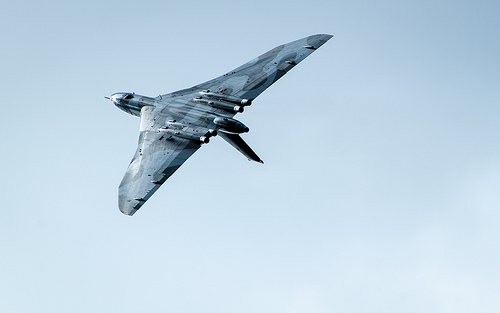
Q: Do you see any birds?
A: No, there are no birds.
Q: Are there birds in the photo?
A: No, there are no birds.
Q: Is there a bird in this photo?
A: No, there are no birds.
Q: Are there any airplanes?
A: Yes, there is an airplane.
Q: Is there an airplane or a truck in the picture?
A: Yes, there is an airplane.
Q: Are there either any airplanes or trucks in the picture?
A: Yes, there is an airplane.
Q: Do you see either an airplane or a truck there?
A: Yes, there is an airplane.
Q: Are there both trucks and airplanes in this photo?
A: No, there is an airplane but no trucks.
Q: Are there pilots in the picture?
A: No, there are no pilots.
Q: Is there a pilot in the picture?
A: No, there are no pilots.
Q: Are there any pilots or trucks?
A: No, there are no pilots or trucks.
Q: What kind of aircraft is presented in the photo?
A: The aircraft is an airplane.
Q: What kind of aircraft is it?
A: The aircraft is an airplane.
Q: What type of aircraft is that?
A: This is an airplane.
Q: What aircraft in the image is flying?
A: The aircraft is an airplane.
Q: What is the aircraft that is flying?
A: The aircraft is an airplane.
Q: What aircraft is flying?
A: The aircraft is an airplane.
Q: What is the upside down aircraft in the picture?
A: The aircraft is an airplane.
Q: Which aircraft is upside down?
A: The aircraft is an airplane.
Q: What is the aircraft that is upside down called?
A: The aircraft is an airplane.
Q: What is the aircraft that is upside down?
A: The aircraft is an airplane.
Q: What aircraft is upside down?
A: The aircraft is an airplane.